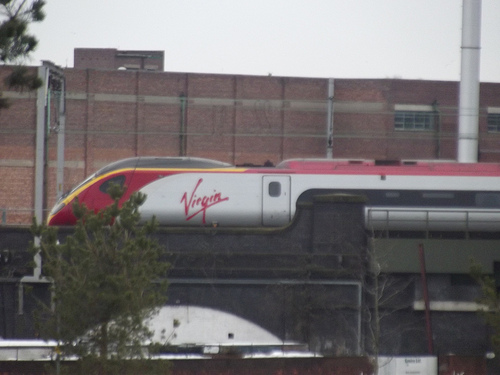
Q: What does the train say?
A: Virgin.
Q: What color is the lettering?
A: Red.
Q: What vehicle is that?
A: Train.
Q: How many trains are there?
A: One.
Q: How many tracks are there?
A: One.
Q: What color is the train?
A: Red and white.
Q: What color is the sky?
A: White.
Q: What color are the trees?
A: Green.